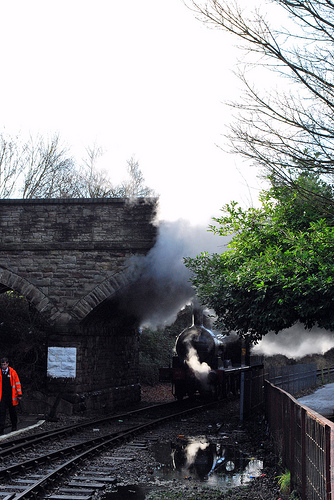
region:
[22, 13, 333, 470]
a scene outside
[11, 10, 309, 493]
a scene happening during the day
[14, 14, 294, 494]
a scene of a train on tracks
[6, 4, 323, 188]
a sky that is white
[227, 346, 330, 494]
a fence on the right side of tracks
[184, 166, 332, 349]
a tree hanging over the fence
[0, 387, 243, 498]
a track that is curving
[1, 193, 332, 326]
a stone bride over the train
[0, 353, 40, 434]
a man in an orange jacket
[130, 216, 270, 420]
a black train that has steam coming out of it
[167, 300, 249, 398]
a black steam train engine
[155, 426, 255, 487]
a large water puddle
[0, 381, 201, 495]
a set of train tracks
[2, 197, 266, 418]
a grey stone bridge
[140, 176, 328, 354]
white steam from train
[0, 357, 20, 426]
a man walking on train tracks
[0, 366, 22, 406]
an orange safety vest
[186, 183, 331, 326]
a large green tree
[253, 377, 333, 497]
a tall protective wall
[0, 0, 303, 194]
a white hazy sky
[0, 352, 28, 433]
man in orange jacket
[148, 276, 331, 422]
old black steam engine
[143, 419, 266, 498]
train reflected in puddle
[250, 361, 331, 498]
old rusty iron fence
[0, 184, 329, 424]
train going under bridge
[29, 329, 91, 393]
white paint over bricks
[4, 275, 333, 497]
steam engine on track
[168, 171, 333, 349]
small green leafy tree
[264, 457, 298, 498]
patch of grass in rocks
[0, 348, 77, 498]
man on railroad tracks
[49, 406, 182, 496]
a railroad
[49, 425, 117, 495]
a railroad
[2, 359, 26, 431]
A man is standing around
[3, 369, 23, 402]
The jacket is orange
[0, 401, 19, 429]
The pants are black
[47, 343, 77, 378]
White paint on the bridge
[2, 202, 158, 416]
A brick bridge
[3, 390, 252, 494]
Some railroad tracks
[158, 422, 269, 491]
A puddle of water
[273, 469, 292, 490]
Green grass near the fence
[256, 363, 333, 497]
A metal fence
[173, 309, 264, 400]
A steam train approaches